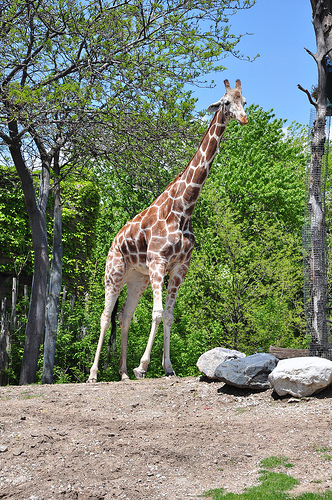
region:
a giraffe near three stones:
[75, 68, 326, 406]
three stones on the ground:
[186, 329, 330, 412]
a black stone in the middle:
[185, 331, 329, 408]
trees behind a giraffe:
[6, 7, 330, 381]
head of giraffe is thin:
[209, 71, 259, 133]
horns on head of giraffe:
[219, 71, 247, 94]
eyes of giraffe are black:
[217, 95, 251, 109]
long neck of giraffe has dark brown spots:
[170, 111, 228, 214]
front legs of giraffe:
[138, 260, 185, 381]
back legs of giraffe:
[84, 275, 130, 385]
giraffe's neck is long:
[175, 110, 211, 224]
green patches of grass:
[239, 455, 279, 499]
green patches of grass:
[208, 473, 242, 497]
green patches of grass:
[262, 444, 305, 493]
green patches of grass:
[278, 464, 324, 499]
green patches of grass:
[266, 441, 285, 483]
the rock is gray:
[212, 343, 274, 400]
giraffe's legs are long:
[87, 239, 209, 455]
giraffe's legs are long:
[130, 260, 186, 399]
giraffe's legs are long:
[78, 272, 158, 419]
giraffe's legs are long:
[151, 273, 194, 422]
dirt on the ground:
[89, 390, 105, 467]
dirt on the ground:
[177, 412, 246, 472]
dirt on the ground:
[120, 387, 194, 437]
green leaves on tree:
[1, 1, 259, 150]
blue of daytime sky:
[195, 0, 315, 116]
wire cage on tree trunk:
[302, 108, 329, 356]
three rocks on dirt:
[195, 348, 331, 395]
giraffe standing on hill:
[87, 78, 248, 385]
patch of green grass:
[259, 454, 295, 469]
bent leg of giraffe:
[133, 263, 163, 379]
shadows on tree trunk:
[24, 230, 45, 381]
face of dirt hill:
[9, 375, 329, 498]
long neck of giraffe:
[173, 111, 228, 215]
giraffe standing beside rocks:
[63, 72, 256, 379]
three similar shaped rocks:
[196, 341, 329, 404]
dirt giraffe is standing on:
[7, 372, 310, 496]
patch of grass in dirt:
[206, 447, 323, 499]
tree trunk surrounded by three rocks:
[299, 15, 331, 356]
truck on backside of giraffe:
[4, 18, 125, 378]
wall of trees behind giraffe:
[9, 106, 312, 359]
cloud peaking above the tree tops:
[2, 120, 71, 170]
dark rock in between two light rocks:
[212, 348, 272, 389]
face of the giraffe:
[208, 79, 252, 127]